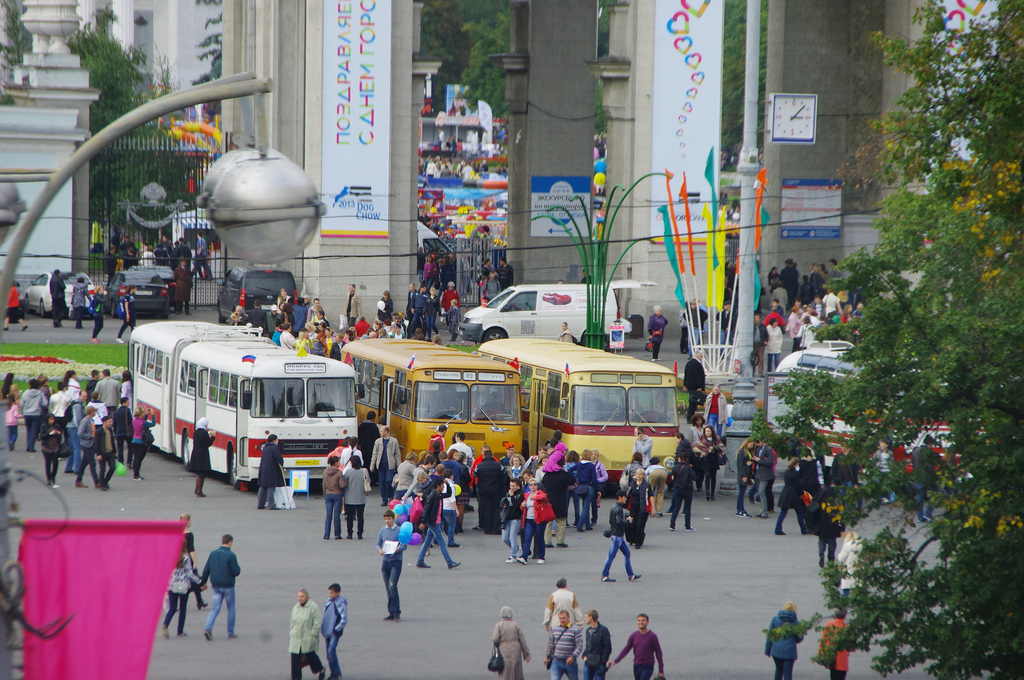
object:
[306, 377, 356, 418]
window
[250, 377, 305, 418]
window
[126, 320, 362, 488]
bus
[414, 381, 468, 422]
window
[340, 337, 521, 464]
bus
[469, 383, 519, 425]
window